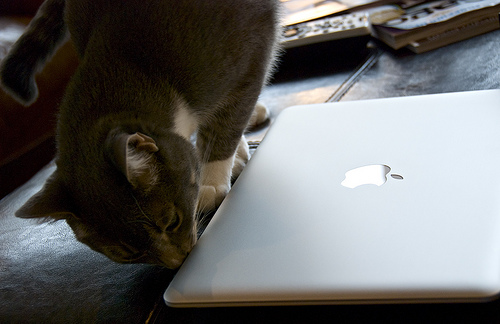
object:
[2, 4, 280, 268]
cat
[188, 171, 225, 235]
whiskers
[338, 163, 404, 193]
logo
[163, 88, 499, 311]
laptop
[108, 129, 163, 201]
ears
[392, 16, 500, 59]
magazines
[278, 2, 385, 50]
remote control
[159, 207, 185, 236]
eyes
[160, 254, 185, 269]
nose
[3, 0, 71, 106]
tail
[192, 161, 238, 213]
paws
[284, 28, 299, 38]
button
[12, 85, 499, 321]
desk